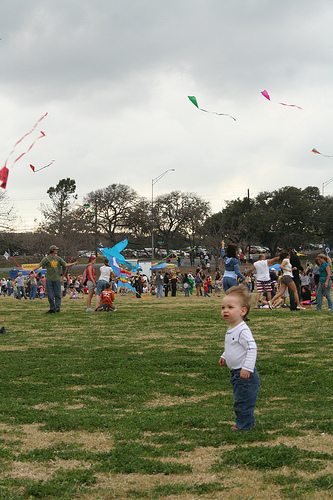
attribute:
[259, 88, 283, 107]
kite — big, streaming, light blue, red, flying, flown, pink, blue, green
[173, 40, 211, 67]
sky — cloudy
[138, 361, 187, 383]
grass — patchy, short, green, here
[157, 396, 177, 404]
dirt — here, brown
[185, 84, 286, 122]
kites — three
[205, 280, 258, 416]
toddler — standing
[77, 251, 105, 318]
man — kneeling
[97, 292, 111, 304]
shirt — green, white, red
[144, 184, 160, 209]
post — unlit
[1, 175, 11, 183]
sign — red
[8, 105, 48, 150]
tail — streaming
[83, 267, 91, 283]
tank top — red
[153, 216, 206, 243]
trees — clustered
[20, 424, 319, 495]
dirt — brown